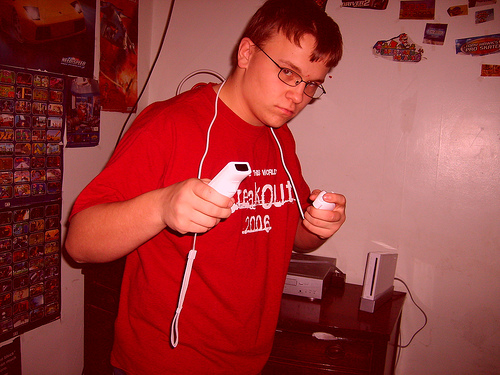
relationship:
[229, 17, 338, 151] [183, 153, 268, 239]
boy holding controller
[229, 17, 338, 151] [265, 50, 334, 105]
boy with eyeglasses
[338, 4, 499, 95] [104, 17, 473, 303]
stickers on wall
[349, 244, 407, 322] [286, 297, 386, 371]
wii on drawer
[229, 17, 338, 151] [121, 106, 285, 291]
boy wearing tshirt